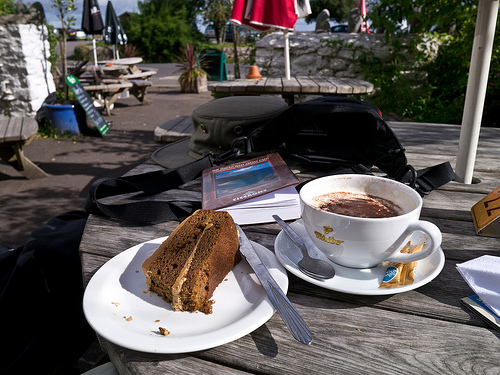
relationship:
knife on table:
[230, 221, 317, 347] [75, 112, 497, 373]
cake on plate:
[139, 207, 242, 318] [81, 227, 290, 355]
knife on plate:
[230, 221, 316, 348] [81, 227, 290, 355]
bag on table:
[82, 104, 458, 239] [75, 112, 497, 373]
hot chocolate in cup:
[326, 189, 398, 220] [290, 154, 444, 274]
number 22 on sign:
[482, 187, 499, 218] [464, 180, 499, 233]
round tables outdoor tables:
[78, 118, 499, 373] [88, 157, 154, 259]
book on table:
[202, 160, 283, 263] [111, 162, 144, 212]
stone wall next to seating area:
[251, 30, 496, 106] [3, 80, 176, 139]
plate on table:
[60, 202, 344, 369] [285, 319, 471, 375]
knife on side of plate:
[230, 221, 317, 347] [82, 310, 249, 373]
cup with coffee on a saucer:
[295, 174, 424, 215] [308, 265, 436, 345]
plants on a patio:
[173, 39, 205, 95] [116, 50, 460, 135]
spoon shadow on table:
[272, 200, 360, 287] [245, 337, 437, 375]